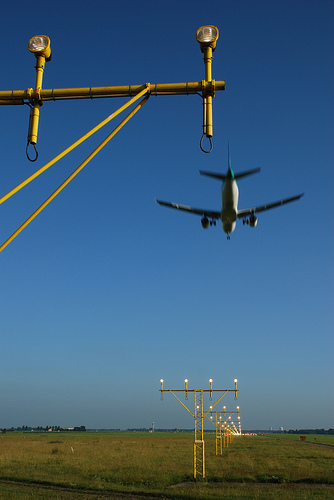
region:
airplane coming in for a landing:
[147, 148, 321, 241]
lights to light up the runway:
[179, 368, 244, 472]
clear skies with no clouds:
[80, 282, 248, 348]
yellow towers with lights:
[154, 367, 247, 477]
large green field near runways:
[23, 414, 300, 491]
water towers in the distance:
[260, 420, 293, 435]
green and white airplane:
[141, 138, 324, 235]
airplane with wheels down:
[133, 146, 317, 247]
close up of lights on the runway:
[10, 23, 239, 163]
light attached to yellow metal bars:
[188, 23, 223, 54]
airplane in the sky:
[139, 138, 305, 241]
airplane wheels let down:
[207, 215, 219, 226]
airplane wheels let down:
[238, 213, 250, 225]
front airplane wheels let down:
[224, 232, 233, 241]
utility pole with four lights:
[158, 373, 239, 480]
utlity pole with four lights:
[194, 401, 243, 454]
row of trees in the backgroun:
[127, 427, 331, 431]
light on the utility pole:
[232, 376, 239, 384]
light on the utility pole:
[206, 375, 215, 383]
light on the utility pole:
[158, 375, 165, 383]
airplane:
[141, 151, 305, 246]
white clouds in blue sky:
[37, 324, 122, 386]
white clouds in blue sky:
[296, 344, 311, 378]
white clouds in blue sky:
[103, 195, 145, 250]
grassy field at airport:
[0, 431, 328, 497]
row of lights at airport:
[157, 378, 240, 477]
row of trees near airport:
[0, 424, 86, 430]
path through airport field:
[0, 476, 197, 498]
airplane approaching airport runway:
[154, 142, 305, 241]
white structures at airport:
[267, 426, 282, 429]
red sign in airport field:
[297, 435, 307, 440]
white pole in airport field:
[69, 445, 74, 453]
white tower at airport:
[151, 421, 153, 430]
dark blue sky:
[0, 0, 331, 427]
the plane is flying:
[124, 143, 299, 286]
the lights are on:
[117, 356, 251, 408]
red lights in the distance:
[211, 418, 259, 439]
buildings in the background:
[11, 413, 91, 432]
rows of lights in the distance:
[182, 376, 254, 475]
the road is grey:
[1, 474, 75, 495]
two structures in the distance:
[255, 414, 287, 434]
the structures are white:
[250, 414, 288, 433]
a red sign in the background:
[289, 429, 311, 443]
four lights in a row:
[133, 363, 247, 396]